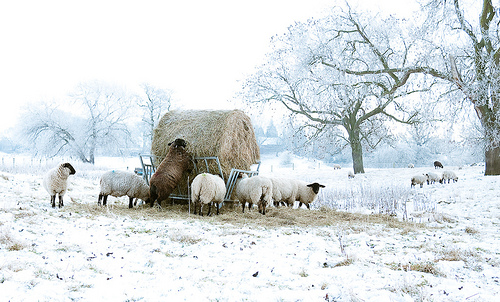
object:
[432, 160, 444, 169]
sheep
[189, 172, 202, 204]
rear end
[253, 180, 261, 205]
rear end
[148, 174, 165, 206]
rear end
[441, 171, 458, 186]
sheep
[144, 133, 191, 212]
sheep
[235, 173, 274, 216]
sheep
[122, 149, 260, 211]
bars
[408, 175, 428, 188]
herd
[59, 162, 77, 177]
head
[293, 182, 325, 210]
sheep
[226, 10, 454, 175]
tree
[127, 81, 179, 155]
tree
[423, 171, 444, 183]
sheep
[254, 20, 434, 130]
branches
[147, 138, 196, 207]
brown sheep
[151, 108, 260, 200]
hay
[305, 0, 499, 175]
trees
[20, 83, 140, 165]
trees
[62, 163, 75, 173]
face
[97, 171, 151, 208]
sheep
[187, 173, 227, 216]
sheep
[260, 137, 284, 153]
building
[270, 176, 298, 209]
sheep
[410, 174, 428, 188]
sheep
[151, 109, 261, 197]
bale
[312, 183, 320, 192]
face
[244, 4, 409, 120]
snow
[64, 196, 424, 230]
hay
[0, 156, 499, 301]
ground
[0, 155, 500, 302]
snow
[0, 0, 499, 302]
outside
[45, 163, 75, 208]
herd